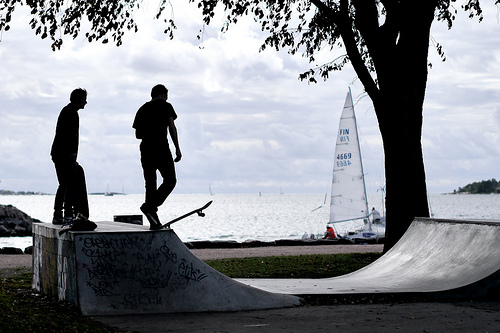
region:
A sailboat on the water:
[303, 88, 383, 240]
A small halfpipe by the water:
[28, 215, 498, 315]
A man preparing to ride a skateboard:
[134, 83, 212, 230]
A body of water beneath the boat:
[2, 195, 499, 237]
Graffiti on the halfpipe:
[76, 235, 209, 313]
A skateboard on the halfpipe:
[161, 199, 215, 226]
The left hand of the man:
[174, 150, 184, 162]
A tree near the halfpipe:
[0, 2, 497, 254]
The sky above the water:
[0, 0, 498, 192]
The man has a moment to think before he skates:
[125, 88, 219, 230]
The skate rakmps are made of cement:
[31, 209, 496, 311]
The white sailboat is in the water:
[323, 89, 383, 240]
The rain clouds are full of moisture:
[208, 94, 328, 165]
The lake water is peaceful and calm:
[224, 191, 293, 237]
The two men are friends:
[37, 87, 181, 231]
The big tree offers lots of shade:
[374, 1, 441, 254]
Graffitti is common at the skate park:
[80, 238, 200, 299]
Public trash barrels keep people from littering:
[110, 209, 146, 226]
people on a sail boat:
[322, 80, 381, 245]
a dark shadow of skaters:
[43, 78, 227, 231]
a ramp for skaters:
[20, 191, 492, 298]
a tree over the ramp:
[344, 49, 454, 241]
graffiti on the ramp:
[77, 237, 177, 323]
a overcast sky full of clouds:
[186, 65, 304, 162]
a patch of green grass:
[220, 255, 339, 277]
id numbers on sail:
[336, 145, 363, 184]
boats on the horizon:
[208, 178, 308, 199]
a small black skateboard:
[152, 201, 221, 232]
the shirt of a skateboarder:
[135, 97, 172, 139]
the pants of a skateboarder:
[128, 147, 182, 201]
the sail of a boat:
[315, 98, 383, 236]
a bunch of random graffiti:
[65, 249, 187, 315]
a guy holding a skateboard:
[62, 158, 98, 228]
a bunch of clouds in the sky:
[195, 66, 294, 179]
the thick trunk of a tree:
[366, 91, 444, 233]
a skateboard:
[145, 183, 217, 228]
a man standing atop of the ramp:
[129, 76, 207, 224]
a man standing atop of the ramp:
[39, 78, 97, 233]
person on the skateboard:
[100, 53, 221, 202]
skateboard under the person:
[137, 191, 216, 259]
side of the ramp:
[55, 222, 210, 314]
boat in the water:
[253, 85, 400, 270]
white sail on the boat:
[281, 95, 382, 225]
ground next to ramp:
[289, 300, 377, 332]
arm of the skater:
[155, 111, 201, 168]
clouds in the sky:
[228, 88, 303, 151]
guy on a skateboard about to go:
[131, 80, 218, 230]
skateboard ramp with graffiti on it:
[27, 214, 499, 318]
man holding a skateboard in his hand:
[51, 86, 89, 225]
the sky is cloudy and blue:
[0, 0, 496, 189]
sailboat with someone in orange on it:
[300, 90, 383, 240]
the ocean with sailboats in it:
[0, 192, 497, 247]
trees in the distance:
[445, 176, 496, 193]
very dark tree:
[0, 0, 498, 258]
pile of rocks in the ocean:
[0, 202, 43, 237]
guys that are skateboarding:
[49, 83, 213, 232]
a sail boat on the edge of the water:
[332, 75, 392, 248]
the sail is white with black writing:
[323, 84, 361, 227]